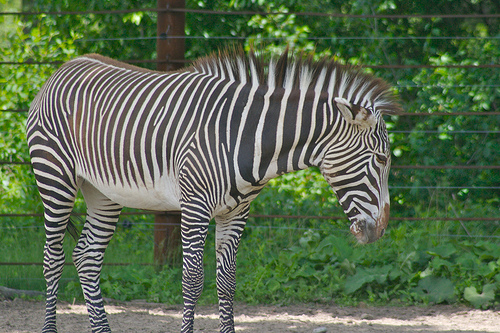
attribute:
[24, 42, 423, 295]
zebra — black and white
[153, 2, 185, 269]
pole — wooden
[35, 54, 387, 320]
zebra — black and white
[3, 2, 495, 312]
trees — green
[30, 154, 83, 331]
leg — striped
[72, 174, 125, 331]
leg — striped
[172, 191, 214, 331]
leg — striped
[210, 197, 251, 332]
leg — striped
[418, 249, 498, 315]
green leaf — large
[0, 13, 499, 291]
fence — black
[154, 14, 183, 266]
pole — brown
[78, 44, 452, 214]
zebra — black, white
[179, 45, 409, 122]
zebra mane — black, white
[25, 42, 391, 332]
zebra — black and white, striped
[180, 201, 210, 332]
leg — black and white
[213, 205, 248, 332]
leg — black and white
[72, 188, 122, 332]
leg — black and white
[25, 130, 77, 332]
leg — black and white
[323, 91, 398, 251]
head — black and white